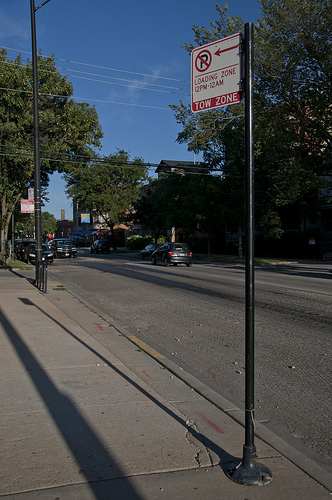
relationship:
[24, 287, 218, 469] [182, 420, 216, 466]
sidewalk has cracks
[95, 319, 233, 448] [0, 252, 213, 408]
paint on sidewalk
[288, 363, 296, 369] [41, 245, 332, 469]
stone in road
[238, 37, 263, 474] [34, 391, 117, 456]
pole has shadow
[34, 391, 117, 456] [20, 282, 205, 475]
shadow on sidewalk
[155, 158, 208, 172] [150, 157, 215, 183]
roof on building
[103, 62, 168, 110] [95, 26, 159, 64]
cloud in sky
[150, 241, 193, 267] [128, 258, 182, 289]
car on road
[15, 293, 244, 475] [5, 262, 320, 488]
shadows on sidewalk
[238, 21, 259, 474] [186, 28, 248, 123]
pole holding up sign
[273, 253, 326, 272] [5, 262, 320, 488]
curb of sidewalk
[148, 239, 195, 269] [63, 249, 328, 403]
car in street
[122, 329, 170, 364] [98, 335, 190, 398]
writing on curb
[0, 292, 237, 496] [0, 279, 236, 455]
shadows on sidewalk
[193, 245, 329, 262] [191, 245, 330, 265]
shadows on sidewalk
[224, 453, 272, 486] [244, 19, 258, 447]
base of pole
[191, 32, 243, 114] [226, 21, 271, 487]
sign on pole